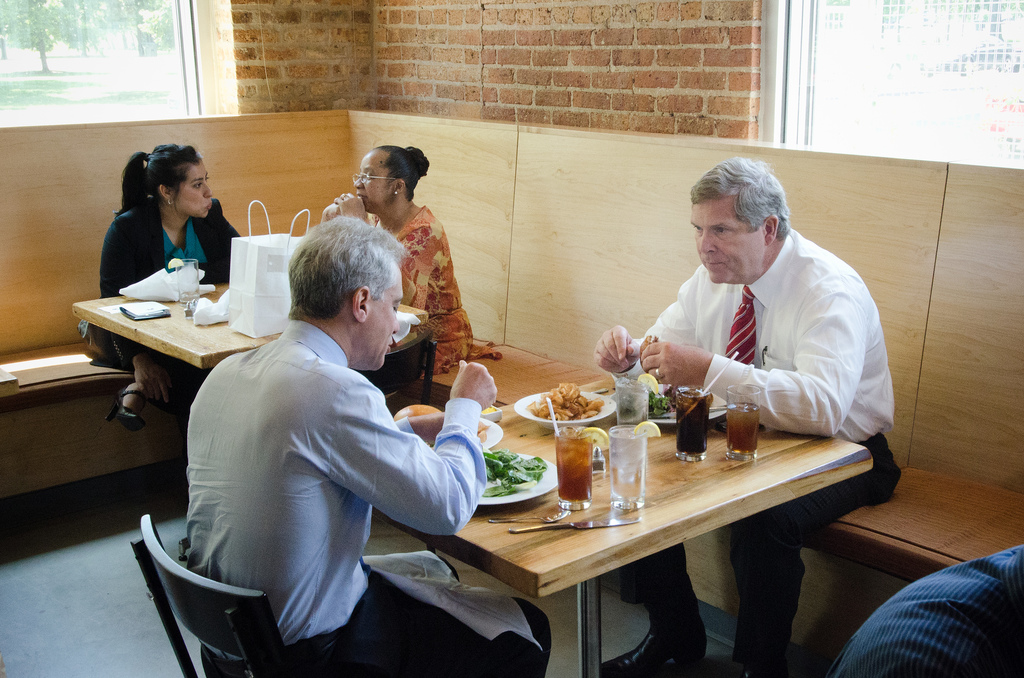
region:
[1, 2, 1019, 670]
the people sitting in the restaurant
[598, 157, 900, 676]
the man is wearing a tie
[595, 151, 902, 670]
the man has gray hair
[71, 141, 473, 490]
the women sitting at the table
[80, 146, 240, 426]
the woman has black hair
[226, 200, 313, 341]
the white bag has handles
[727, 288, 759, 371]
the red tie has white stripes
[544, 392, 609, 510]
the straw in the cup with brown tea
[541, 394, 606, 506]
the slice of lemon on the cup with tea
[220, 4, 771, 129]
red brick wall behind wood bench seating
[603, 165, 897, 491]
businessman wearing white dress shirt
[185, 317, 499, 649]
light blue dress shirt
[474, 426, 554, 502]
plate os dark green salad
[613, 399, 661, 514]
glass of water with a lemon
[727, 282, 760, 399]
red necktie with diagonal stripes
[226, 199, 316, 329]
white paper shopping bag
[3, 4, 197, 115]
tree and green lawn seen out the window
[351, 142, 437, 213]
person wears a tight bun and metal framed glasses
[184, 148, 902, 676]
two men sitting down at a table and eating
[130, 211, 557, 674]
man sitting on black chair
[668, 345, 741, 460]
glass of pop with white straw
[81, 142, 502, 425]
two women sitting at a table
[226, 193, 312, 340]
white paper bag on top of table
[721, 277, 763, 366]
red and white striped tie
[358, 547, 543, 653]
white napkin on a lap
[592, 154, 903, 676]
man wearing shiny black shoes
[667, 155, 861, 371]
man eating at table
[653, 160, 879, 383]
man wearing white shirt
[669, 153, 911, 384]
man wearing red tie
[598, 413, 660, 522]
glass on a table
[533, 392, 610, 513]
glass on a table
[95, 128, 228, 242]
woman sitting at a table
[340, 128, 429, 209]
woman sitting at a table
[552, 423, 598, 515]
a glass of tea on a table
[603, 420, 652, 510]
a glass of water on a table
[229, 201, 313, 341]
a white bag on a table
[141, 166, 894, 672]
a couple of men eating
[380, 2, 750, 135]
a brown brick wall.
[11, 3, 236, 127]
a glass window on a wall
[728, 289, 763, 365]
a red stripped tie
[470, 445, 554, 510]
a white plate with salad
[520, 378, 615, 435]
a white plate of food on a table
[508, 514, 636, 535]
a silver knife on a table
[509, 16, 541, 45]
a red brick on the wall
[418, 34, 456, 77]
a red brick on the wall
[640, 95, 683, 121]
a red brick on the wall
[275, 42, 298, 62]
a red brick on the wall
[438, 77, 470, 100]
a red brick on the wall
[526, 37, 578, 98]
a red brick on the wall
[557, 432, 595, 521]
ice tea in a glass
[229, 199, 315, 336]
white paper bag on the table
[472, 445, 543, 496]
green salad on the dinner plate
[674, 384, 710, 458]
a glass of coke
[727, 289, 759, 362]
red and white strip tie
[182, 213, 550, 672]
man in a blue dress shirt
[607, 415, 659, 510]
glass of water with a lemon wedge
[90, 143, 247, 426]
woman in a black suit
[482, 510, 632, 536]
silver utensils on the table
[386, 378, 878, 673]
table filled with different foods